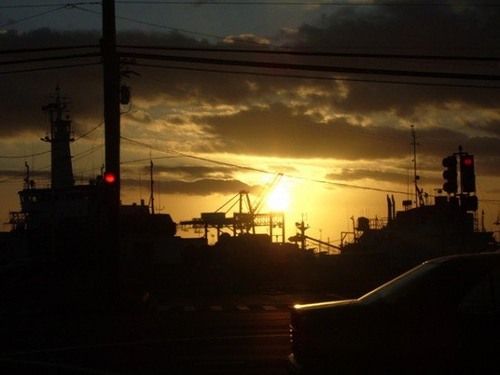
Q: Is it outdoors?
A: Yes, it is outdoors.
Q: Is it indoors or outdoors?
A: It is outdoors.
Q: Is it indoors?
A: No, it is outdoors.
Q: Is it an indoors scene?
A: No, it is outdoors.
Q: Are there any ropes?
A: No, there are no ropes.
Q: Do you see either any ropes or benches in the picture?
A: No, there are no ropes or benches.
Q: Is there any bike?
A: No, there are no bikes.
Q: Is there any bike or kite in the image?
A: No, there are no bikes or kites.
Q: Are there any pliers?
A: No, there are no pliers.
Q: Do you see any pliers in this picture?
A: No, there are no pliers.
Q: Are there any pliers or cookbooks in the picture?
A: No, there are no pliers or cookbooks.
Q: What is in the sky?
A: The sun is in the sky.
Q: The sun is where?
A: The sun is in the sky.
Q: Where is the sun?
A: The sun is in the sky.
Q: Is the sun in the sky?
A: Yes, the sun is in the sky.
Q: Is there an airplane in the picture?
A: No, there are no airplanes.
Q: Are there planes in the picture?
A: No, there are no planes.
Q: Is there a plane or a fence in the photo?
A: No, there are no airplanes or fences.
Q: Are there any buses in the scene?
A: No, there are no buses.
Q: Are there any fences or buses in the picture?
A: No, there are no buses or fences.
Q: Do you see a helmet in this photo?
A: No, there are no helmets.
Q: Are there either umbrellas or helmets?
A: No, there are no helmets or umbrellas.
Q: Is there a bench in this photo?
A: No, there are no benches.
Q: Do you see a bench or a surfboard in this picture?
A: No, there are no benches or surfboards.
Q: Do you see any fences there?
A: No, there are no fences.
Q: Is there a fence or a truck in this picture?
A: No, there are no fences or trucks.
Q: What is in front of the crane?
A: The car is in front of the crane.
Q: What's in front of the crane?
A: The car is in front of the crane.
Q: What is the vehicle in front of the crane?
A: The vehicle is a car.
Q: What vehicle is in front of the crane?
A: The vehicle is a car.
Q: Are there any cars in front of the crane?
A: Yes, there is a car in front of the crane.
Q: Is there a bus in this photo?
A: No, there are no buses.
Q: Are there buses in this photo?
A: No, there are no buses.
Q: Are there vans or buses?
A: No, there are no buses or vans.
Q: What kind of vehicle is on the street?
A: The vehicle is a car.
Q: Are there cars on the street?
A: Yes, there is a car on the street.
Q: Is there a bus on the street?
A: No, there is a car on the street.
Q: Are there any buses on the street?
A: No, there is a car on the street.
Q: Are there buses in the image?
A: No, there are no buses.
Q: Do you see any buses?
A: No, there are no buses.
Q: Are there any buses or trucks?
A: No, there are no buses or trucks.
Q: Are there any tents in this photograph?
A: No, there are no tents.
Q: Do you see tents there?
A: No, there are no tents.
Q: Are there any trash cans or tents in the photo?
A: No, there are no tents or trash cans.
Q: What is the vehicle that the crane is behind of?
A: The vehicle is a car.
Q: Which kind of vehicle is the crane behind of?
A: The crane is behind the car.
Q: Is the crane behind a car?
A: Yes, the crane is behind a car.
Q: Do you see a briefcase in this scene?
A: No, there are no briefcases.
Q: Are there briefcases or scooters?
A: No, there are no briefcases or scooters.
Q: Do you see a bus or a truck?
A: No, there are no buses or trucks.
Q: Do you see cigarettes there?
A: No, there are no cigarettes.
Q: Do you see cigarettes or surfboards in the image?
A: No, there are no cigarettes or surfboards.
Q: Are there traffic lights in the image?
A: Yes, there is a traffic light.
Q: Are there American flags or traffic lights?
A: Yes, there is a traffic light.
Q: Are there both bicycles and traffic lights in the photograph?
A: No, there is a traffic light but no bikes.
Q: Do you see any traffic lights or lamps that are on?
A: Yes, the traffic light is on.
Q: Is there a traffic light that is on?
A: Yes, there is a traffic light that is on.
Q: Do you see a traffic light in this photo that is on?
A: Yes, there is a traffic light that is on.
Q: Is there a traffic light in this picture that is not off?
A: Yes, there is a traffic light that is on.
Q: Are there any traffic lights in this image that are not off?
A: Yes, there is a traffic light that is on.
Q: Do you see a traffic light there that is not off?
A: Yes, there is a traffic light that is on .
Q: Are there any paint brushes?
A: No, there are no paint brushes.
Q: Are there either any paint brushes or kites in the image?
A: No, there are no paint brushes or kites.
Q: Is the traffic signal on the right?
A: Yes, the traffic signal is on the right of the image.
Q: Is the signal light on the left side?
A: No, the signal light is on the right of the image.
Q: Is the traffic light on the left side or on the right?
A: The traffic light is on the right of the image.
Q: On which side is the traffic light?
A: The traffic light is on the right of the image.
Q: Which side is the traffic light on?
A: The traffic light is on the right of the image.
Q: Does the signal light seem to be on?
A: Yes, the signal light is on.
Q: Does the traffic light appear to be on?
A: Yes, the traffic light is on.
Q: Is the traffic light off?
A: No, the traffic light is on.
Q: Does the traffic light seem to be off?
A: No, the traffic light is on.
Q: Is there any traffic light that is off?
A: No, there is a traffic light but it is on.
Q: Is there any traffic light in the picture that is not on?
A: No, there is a traffic light but it is on.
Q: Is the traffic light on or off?
A: The traffic light is on.